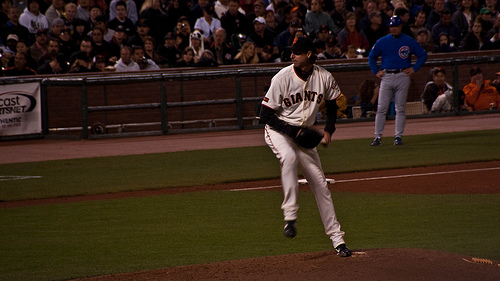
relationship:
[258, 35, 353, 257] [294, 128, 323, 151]
player wear glove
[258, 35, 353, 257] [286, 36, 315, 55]
player wearing cap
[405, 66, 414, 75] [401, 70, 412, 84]
hand in pocket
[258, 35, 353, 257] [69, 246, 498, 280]
player on mound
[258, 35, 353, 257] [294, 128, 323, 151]
player holding glove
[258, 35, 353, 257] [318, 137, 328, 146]
player has baseball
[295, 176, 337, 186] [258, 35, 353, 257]
base behind player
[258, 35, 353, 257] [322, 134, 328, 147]
player holding baseball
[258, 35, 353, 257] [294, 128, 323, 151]
player wearing glove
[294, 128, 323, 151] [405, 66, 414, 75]
glove on hand